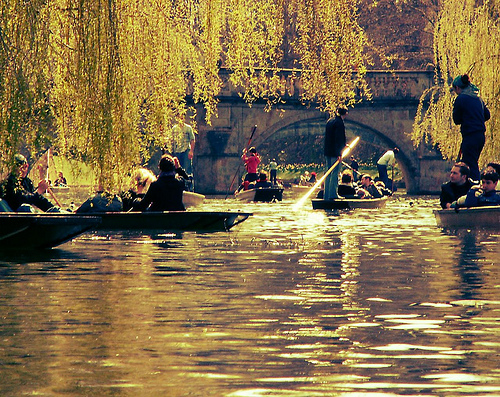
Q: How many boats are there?
A: Six.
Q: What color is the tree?
A: Green.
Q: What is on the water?
A: Reflection.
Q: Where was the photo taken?
A: River.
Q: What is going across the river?
A: Bridge.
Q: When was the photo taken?
A: Morning.